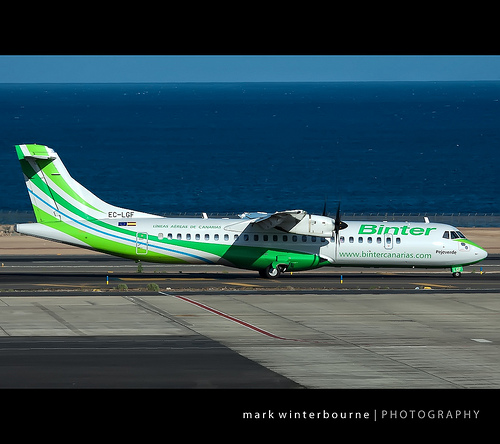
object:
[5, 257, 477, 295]
runway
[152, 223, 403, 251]
windows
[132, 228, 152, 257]
door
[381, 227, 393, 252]
door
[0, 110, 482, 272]
plane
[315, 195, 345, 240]
propellers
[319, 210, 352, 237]
plane engine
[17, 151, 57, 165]
stabilizer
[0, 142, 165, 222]
plane tail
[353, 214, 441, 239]
name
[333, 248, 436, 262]
email address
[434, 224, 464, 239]
windows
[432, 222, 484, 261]
cockpit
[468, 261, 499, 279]
airport runway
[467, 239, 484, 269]
nose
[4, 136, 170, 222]
tail wing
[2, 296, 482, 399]
runway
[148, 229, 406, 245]
windows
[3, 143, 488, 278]
airplane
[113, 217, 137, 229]
flag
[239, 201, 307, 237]
wing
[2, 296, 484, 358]
runway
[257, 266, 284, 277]
wheels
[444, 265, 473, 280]
landing gear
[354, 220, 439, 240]
letters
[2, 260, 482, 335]
tarmac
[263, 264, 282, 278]
landing gear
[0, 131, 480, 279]
plane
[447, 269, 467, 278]
landing gear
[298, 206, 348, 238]
right engine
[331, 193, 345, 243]
propeller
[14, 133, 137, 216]
tail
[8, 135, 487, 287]
plane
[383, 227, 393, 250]
front door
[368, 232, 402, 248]
windows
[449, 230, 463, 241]
windshield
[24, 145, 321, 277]
stripes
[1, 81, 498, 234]
water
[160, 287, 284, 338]
line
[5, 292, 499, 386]
runway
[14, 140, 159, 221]
plane tail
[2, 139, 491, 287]
windows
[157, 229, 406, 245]
plane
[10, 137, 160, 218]
tail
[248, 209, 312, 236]
wing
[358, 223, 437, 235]
binter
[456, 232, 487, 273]
nose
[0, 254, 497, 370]
runway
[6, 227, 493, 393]
ground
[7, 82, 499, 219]
water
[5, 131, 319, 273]
stripes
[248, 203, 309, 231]
wing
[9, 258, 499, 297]
strip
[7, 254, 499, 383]
runway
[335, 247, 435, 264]
website url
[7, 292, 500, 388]
ground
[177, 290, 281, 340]
line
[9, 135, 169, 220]
tail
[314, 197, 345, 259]
propellers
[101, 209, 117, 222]
letters